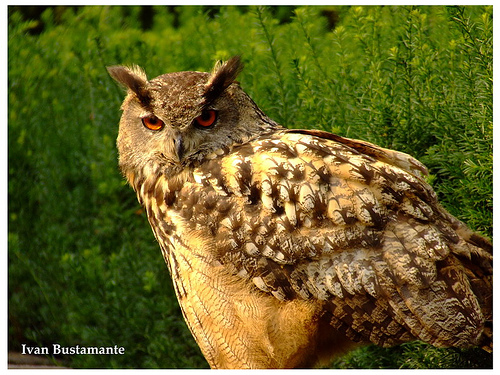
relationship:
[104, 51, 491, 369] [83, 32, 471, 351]
owl in trees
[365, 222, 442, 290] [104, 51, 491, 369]
feather on owl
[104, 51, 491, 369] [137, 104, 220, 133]
owl has eyes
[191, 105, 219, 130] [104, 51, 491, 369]
eye on owl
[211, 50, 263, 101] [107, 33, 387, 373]
ear on owl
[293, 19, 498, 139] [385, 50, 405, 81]
trees have pine needle